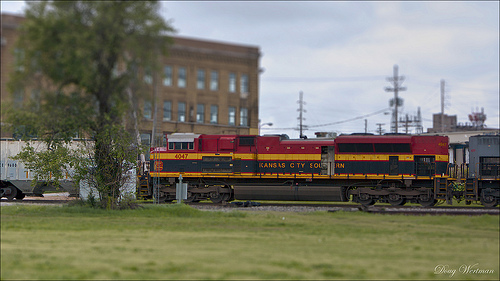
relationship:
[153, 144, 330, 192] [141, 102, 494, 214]
letter on train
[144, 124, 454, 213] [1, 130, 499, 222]
car on train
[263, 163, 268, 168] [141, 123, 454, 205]
letter on train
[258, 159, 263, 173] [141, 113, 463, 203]
letter on train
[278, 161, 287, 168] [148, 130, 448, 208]
letter on train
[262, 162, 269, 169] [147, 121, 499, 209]
letter on train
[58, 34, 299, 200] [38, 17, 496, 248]
wall on side of a building